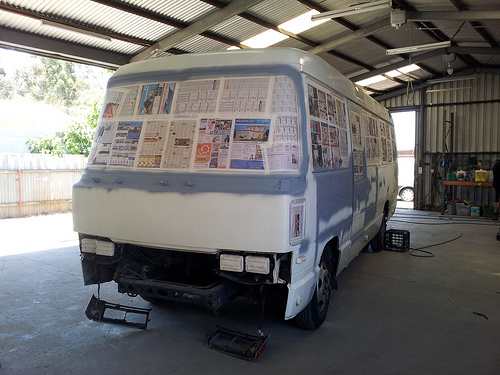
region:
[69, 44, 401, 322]
a passenger van is ready for painting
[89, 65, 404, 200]
newspaper is taped to the windows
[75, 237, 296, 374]
the front bumper is off the van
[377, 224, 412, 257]
an egg crate is next to the van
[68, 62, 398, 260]
the van has been sanded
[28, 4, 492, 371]
the van is in a warehouse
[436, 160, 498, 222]
a table is against the wall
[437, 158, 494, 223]
boxes and canisters are near the wall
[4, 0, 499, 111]
the ceilings and walls are corrugated metal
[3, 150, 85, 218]
a fence is behind the warehouse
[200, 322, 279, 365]
fallen van bumper on the ground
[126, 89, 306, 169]
A windshield covered in newspaper.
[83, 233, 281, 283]
Headlights to a van.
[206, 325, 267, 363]
Headlight cover from the left side of the van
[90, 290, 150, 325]
Headlight cover from the right side of the van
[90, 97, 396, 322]
A van being repainted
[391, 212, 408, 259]
A milk crate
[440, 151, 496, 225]
Vehicle painting equiptment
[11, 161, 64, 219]
A wood fence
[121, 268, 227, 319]
Bumper reinforcment to a van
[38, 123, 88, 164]
Trees hanging over the wooden fence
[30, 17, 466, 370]
An old VW van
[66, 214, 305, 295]
Headlights on the van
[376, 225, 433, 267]
A black milk crate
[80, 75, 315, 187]
Newspapers covering the windshield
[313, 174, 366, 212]
Spots of blue paint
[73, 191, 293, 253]
Spots of white paint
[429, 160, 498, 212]
A work table with bottles on it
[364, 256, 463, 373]
A clean garage floor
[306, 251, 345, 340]
one of the tires on the van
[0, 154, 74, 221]
A wooden privacy fence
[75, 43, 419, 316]
A beat up van with lots of graphics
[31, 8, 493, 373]
A van in a garage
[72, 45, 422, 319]
The van is white and grey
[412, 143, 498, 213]
A rack of tools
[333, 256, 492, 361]
Concrete below the van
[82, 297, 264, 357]
Metal parts hanging from the van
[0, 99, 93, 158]
A building behind the fence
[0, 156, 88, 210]
A wooden fence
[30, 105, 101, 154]
A green tree behind the fence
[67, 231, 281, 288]
The van's headlights are not on